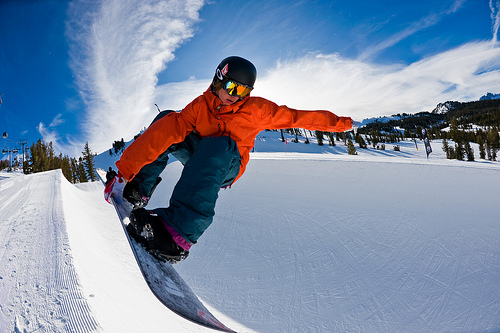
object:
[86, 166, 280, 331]
slope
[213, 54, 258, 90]
helmet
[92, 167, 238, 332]
board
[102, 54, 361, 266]
he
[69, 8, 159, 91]
cloud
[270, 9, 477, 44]
sky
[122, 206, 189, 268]
boots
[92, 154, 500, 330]
half pipe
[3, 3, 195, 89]
sky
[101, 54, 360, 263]
boy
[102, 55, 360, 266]
man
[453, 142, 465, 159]
leaves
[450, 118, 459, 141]
tree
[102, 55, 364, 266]
man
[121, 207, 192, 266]
feet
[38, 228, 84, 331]
lines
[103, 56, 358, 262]
he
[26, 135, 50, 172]
patch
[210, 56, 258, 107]
head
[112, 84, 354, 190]
jacket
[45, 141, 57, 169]
tree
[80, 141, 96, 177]
tree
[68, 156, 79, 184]
tree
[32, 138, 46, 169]
tree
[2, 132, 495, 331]
snow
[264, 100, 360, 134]
arm